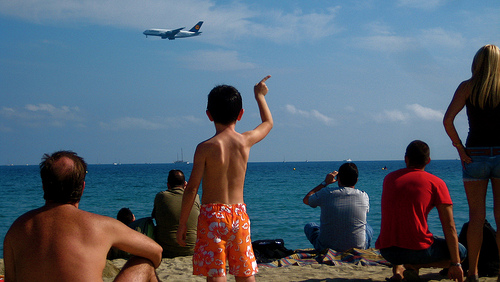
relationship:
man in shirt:
[302, 158, 372, 255] [308, 185, 368, 250]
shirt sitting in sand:
[308, 185, 368, 250] [101, 248, 485, 280]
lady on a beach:
[439, 43, 499, 279] [118, 177, 351, 276]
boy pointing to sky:
[180, 76, 272, 279] [0, 1, 495, 166]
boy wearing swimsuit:
[180, 76, 272, 279] [184, 200, 263, 276]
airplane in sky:
[132, 19, 209, 41] [132, 37, 259, 95]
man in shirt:
[369, 134, 469, 280] [393, 165, 428, 194]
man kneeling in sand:
[369, 134, 469, 280] [354, 262, 381, 280]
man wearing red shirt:
[369, 134, 469, 280] [376, 165, 452, 248]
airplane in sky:
[132, 19, 209, 41] [252, 7, 366, 90]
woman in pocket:
[440, 42, 495, 279] [459, 156, 481, 176]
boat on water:
[170, 148, 195, 168] [3, 153, 499, 257]